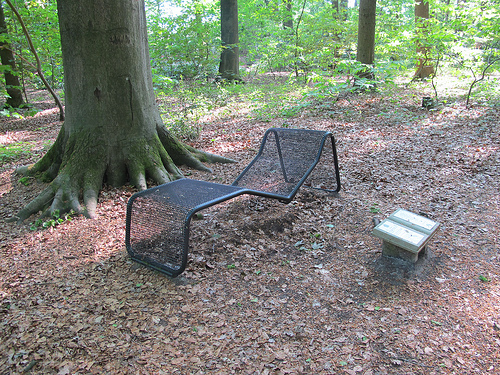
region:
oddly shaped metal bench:
[81, 121, 367, 281]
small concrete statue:
[371, 195, 444, 262]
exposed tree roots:
[16, 127, 224, 224]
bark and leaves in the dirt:
[19, 280, 149, 358]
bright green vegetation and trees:
[352, 4, 497, 113]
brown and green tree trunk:
[50, 5, 180, 153]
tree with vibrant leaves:
[145, 0, 230, 88]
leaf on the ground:
[294, 231, 338, 267]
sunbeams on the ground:
[177, 80, 285, 144]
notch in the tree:
[82, 78, 116, 113]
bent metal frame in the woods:
[110, 112, 349, 292]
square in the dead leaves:
[373, 202, 446, 280]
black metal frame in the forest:
[115, 102, 345, 298]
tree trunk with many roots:
[12, 16, 210, 228]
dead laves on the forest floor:
[209, 268, 302, 355]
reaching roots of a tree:
[11, 173, 107, 238]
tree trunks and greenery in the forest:
[293, 10, 460, 100]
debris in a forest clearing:
[33, 48, 465, 318]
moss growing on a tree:
[46, 126, 116, 181]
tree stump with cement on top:
[364, 198, 448, 275]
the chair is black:
[81, 71, 349, 300]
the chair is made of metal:
[99, 111, 334, 283]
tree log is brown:
[36, 0, 228, 205]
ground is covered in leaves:
[5, 112, 471, 371]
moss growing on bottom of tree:
[26, 108, 250, 213]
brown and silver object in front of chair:
[363, 191, 465, 281]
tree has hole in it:
[72, 65, 114, 104]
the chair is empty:
[93, 83, 420, 309]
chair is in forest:
[48, 3, 465, 341]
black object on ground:
[411, 81, 452, 125]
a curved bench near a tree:
[111, 112, 352, 279]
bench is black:
[114, 121, 346, 289]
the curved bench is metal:
[96, 117, 353, 289]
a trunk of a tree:
[17, 0, 218, 176]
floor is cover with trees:
[2, 111, 497, 369]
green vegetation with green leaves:
[10, 0, 498, 82]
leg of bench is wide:
[107, 205, 199, 285]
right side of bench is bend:
[206, 118, 353, 203]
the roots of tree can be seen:
[6, 148, 223, 214]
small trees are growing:
[386, 8, 493, 108]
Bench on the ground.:
[94, 111, 439, 305]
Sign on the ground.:
[380, 165, 474, 265]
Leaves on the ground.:
[71, 195, 190, 300]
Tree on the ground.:
[16, 20, 333, 302]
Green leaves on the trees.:
[231, 5, 458, 102]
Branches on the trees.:
[382, 54, 483, 113]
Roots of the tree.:
[26, 187, 93, 245]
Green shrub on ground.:
[18, 202, 88, 249]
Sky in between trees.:
[155, 7, 210, 34]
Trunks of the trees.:
[203, 6, 450, 98]